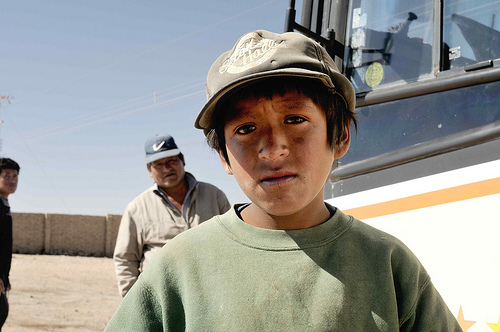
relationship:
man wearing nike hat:
[108, 129, 237, 296] [139, 131, 184, 167]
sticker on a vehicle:
[363, 59, 386, 88] [284, 0, 500, 194]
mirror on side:
[285, 2, 353, 57] [282, 1, 386, 63]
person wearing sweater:
[108, 129, 237, 296] [111, 175, 233, 283]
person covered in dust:
[103, 27, 463, 331] [215, 93, 340, 231]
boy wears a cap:
[103, 27, 463, 331] [190, 27, 361, 134]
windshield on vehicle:
[346, 1, 407, 85] [284, 0, 500, 194]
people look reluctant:
[0, 130, 190, 324] [4, 139, 186, 200]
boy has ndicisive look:
[103, 27, 463, 331] [221, 85, 321, 215]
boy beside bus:
[103, 27, 463, 331] [284, 0, 500, 194]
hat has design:
[190, 27, 361, 134] [216, 30, 285, 79]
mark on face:
[292, 135, 306, 144] [215, 93, 340, 231]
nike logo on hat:
[152, 141, 166, 155] [139, 131, 184, 167]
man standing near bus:
[108, 129, 237, 296] [352, 4, 494, 241]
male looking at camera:
[3, 130, 221, 289] [1, 4, 495, 331]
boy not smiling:
[103, 27, 463, 331] [215, 93, 340, 231]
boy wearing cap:
[103, 27, 463, 331] [190, 27, 361, 134]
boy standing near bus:
[103, 27, 463, 331] [352, 4, 494, 241]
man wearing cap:
[104, 130, 271, 330] [139, 131, 184, 167]